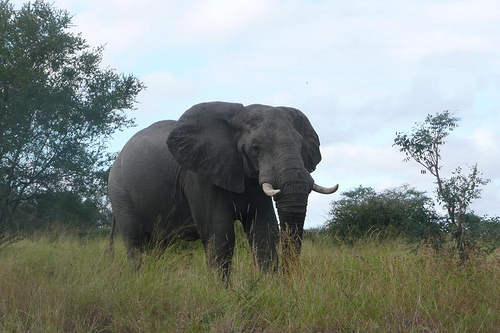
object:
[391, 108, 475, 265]
tree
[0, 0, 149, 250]
tree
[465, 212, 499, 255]
tree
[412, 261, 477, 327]
grass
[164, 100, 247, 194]
ear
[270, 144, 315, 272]
trunk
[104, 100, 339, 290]
elephant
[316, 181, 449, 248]
bush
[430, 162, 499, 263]
tree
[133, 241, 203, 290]
grass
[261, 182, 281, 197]
right tusk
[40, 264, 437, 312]
greengrass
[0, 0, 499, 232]
sky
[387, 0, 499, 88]
clouds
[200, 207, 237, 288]
right leg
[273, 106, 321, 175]
ear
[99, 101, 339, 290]
elephant standing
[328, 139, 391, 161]
light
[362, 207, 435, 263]
grass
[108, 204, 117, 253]
tail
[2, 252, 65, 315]
grass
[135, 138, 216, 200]
skin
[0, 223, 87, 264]
grass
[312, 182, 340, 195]
tusk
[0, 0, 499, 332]
field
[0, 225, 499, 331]
grass